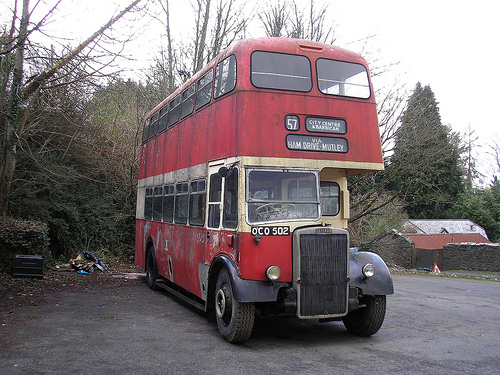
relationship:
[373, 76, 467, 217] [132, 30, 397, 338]
tree to left of bus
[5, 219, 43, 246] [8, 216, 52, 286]
limbs in bin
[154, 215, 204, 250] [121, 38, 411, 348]
rust on bus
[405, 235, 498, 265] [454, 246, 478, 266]
wall made of rocks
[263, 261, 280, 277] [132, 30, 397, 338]
headlight on bus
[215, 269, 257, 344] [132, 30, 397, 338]
tire on bus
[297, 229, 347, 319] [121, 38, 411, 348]
gril on bus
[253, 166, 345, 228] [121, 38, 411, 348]
windshield on bus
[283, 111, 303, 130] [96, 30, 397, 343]
number on bus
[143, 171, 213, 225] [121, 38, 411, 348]
windows on bus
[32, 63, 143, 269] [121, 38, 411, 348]
trees around bus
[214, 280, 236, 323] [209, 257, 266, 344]
rim on tire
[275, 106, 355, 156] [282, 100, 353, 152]
text on background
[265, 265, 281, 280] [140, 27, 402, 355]
headlight on bus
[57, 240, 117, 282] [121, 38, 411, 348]
debris next to bus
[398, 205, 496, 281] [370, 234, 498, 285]
houses behind wall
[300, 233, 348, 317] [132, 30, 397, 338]
gril on bus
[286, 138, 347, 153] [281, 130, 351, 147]
letters on sign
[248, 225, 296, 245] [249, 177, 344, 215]
license under window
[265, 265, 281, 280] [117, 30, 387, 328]
headlight on bus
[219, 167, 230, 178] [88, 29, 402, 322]
mirror on bus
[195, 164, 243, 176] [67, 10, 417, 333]
mirror on bus